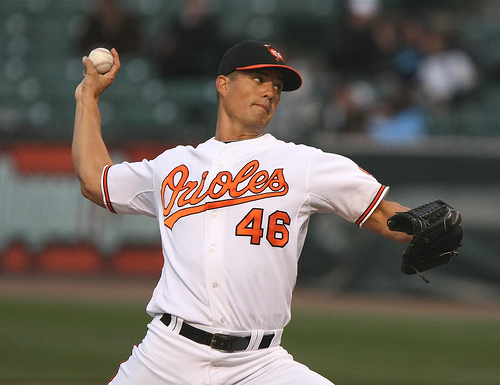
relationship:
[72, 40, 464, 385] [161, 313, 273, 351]
baseball player wearing belt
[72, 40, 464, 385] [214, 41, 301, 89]
baseball player wearing hat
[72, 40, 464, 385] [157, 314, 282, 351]
baseball player wearing belt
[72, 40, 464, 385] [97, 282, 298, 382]
baseball player wearing pants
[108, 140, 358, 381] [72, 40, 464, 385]
jersey of baseball player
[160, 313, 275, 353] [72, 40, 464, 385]
belt of baseball player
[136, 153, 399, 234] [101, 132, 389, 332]
name on jersey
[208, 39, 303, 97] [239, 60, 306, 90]
hat with brim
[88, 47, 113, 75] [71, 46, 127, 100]
ball in hand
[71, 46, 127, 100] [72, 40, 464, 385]
hand of baseball player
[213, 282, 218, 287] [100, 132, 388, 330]
button on jersey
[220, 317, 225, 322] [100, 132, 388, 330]
button on jersey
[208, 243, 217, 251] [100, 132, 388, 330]
button on jersey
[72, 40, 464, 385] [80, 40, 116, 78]
baseball player pitching ball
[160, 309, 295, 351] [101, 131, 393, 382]
belt on pitcher's unifrom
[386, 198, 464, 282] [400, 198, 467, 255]
baseball glove on hand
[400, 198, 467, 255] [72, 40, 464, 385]
hand of baseball player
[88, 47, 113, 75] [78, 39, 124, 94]
ball in hand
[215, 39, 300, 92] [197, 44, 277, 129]
hat on head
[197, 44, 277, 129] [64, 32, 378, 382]
head on man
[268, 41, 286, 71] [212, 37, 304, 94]
oriole on hat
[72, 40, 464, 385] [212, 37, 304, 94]
baseball player wearing hat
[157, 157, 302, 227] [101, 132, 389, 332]
orioles on front of jersey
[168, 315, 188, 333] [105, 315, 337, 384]
belt loops on pants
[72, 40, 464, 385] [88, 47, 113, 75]
baseball player holding ball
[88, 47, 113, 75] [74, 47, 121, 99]
ball in hand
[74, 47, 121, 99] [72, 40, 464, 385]
hand of baseball player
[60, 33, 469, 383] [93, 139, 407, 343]
baseball player wearing jersey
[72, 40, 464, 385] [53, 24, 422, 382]
baseball player playing baseball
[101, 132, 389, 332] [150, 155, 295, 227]
jersey says orioles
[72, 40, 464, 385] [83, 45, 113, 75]
baseball player about throw ball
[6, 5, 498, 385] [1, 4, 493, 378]
baseball game in photo